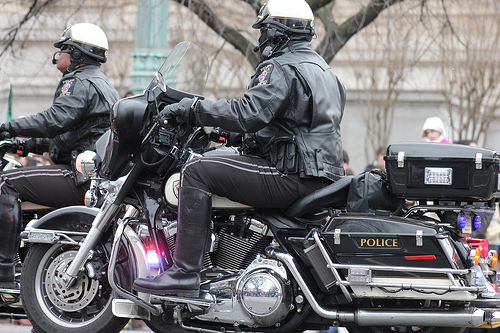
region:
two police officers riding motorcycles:
[3, 1, 499, 331]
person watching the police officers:
[406, 115, 456, 155]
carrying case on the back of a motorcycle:
[378, 138, 498, 200]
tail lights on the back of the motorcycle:
[449, 212, 499, 297]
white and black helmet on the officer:
[247, 0, 337, 57]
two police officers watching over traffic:
[11, 0, 499, 330]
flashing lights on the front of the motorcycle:
[124, 241, 167, 278]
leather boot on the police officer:
[131, 179, 223, 309]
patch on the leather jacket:
[246, 60, 277, 92]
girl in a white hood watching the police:
[413, 115, 450, 145]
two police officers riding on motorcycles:
[6, 2, 492, 322]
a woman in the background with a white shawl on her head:
[415, 111, 450, 141]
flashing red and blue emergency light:
[136, 240, 163, 272]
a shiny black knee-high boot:
[131, 180, 211, 300]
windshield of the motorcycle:
[151, 35, 211, 95]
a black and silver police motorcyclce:
[20, 40, 495, 327]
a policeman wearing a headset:
[0, 10, 115, 205]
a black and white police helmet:
[50, 20, 105, 60]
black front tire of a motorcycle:
[15, 220, 135, 326]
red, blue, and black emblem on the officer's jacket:
[251, 63, 275, 90]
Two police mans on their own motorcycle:
[3, 3, 497, 330]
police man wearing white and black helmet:
[127, 3, 353, 301]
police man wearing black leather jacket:
[134, 0, 329, 307]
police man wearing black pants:
[130, 0, 361, 307]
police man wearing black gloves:
[125, 2, 352, 299]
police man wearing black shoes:
[133, 1, 353, 312]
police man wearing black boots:
[131, 2, 353, 299]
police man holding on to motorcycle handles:
[122, 1, 357, 303]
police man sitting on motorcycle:
[133, 0, 364, 318]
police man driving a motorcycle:
[23, 2, 493, 324]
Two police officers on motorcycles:
[0, 8, 415, 320]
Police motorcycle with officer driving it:
[168, 187, 452, 297]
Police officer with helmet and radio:
[23, 13, 108, 93]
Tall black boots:
[131, 188, 236, 298]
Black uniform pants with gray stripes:
[161, 135, 289, 217]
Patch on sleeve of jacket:
[233, 52, 285, 96]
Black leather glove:
[142, 90, 189, 124]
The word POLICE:
[356, 219, 401, 260]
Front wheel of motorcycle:
[5, 197, 135, 329]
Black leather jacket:
[183, 31, 360, 180]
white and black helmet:
[248, 0, 332, 57]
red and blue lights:
[143, 243, 163, 267]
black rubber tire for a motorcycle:
[15, 223, 135, 331]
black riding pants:
[151, 135, 316, 296]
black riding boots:
[131, 182, 211, 306]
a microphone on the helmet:
[50, 45, 70, 68]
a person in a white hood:
[412, 115, 452, 140]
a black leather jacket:
[190, 32, 371, 195]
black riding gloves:
[140, 94, 199, 140]